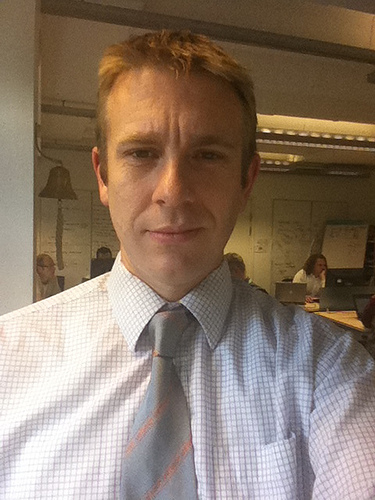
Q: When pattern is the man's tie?
A: Striped.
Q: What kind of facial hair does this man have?
A: None.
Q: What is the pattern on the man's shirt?
A: Checked.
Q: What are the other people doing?
A: Working on computers.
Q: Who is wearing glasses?
A: The man in the back on the left.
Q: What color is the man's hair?
A: Blonde.